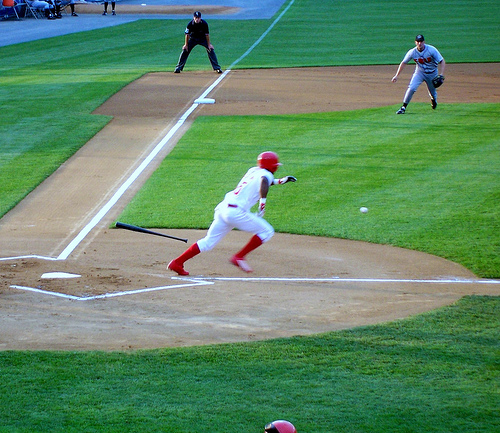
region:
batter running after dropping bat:
[80, 145, 295, 275]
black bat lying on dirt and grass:
[110, 210, 187, 245]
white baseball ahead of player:
[161, 150, 371, 280]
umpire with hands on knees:
[170, 5, 222, 75]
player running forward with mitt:
[390, 30, 445, 111]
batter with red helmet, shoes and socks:
[161, 146, 296, 277]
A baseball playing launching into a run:
[180, 131, 292, 274]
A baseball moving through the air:
[355, 199, 371, 215]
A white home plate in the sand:
[31, 264, 83, 285]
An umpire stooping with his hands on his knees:
[169, 5, 232, 83]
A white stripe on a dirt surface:
[290, 263, 415, 299]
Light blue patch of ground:
[15, 23, 44, 34]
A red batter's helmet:
[250, 152, 285, 168]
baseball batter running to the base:
[167, 133, 295, 290]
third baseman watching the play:
[169, 7, 226, 79]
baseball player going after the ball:
[391, 27, 449, 128]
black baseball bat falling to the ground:
[111, 214, 193, 253]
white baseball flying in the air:
[356, 200, 371, 218]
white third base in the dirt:
[191, 91, 216, 112]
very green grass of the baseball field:
[315, 127, 487, 200]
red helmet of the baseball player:
[256, 149, 281, 170]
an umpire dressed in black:
[175, 11, 223, 74]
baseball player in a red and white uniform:
[167, 149, 296, 276]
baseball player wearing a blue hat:
[390, 33, 445, 111]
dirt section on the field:
[0, 61, 495, 354]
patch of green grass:
[0, 292, 495, 427]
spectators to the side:
[0, 0, 116, 17]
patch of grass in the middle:
[116, 97, 496, 277]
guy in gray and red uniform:
[389, 35, 444, 115]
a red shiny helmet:
[255, 147, 280, 167]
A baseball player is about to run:
[160, 145, 300, 280]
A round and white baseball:
[355, 200, 372, 220]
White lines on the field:
[0, 0, 496, 305]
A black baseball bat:
[110, 212, 192, 247]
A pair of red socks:
[170, 225, 265, 265]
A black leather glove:
[425, 70, 445, 90]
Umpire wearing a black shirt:
[180, 6, 215, 46]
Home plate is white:
[35, 265, 85, 285]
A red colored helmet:
[250, 145, 285, 175]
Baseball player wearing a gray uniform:
[385, 28, 448, 118]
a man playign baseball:
[152, 116, 392, 304]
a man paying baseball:
[379, 15, 444, 125]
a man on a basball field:
[186, 150, 307, 257]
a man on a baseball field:
[357, 22, 485, 133]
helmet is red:
[256, 150, 281, 167]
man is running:
[166, 152, 296, 274]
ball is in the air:
[356, 203, 368, 213]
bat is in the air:
[116, 222, 187, 243]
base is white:
[39, 270, 79, 279]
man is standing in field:
[391, 34, 446, 112]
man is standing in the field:
[174, 9, 221, 76]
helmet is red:
[266, 420, 298, 430]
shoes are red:
[166, 259, 262, 276]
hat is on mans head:
[416, 34, 426, 41]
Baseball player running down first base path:
[165, 146, 297, 277]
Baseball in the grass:
[357, 196, 369, 219]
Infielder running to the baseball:
[388, 32, 444, 117]